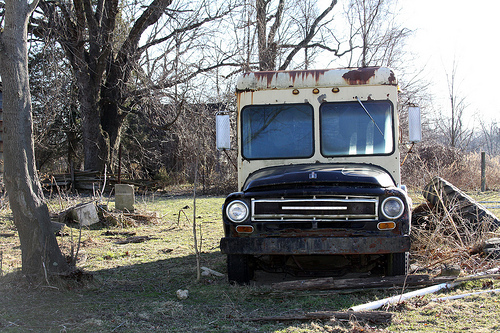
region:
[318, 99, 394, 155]
windshield on right side of truck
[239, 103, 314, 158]
windshield to the left of windshield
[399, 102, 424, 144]
sideview mirror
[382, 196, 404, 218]
headlight is round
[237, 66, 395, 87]
top of truck is rusty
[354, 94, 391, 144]
windshield wiper on windshield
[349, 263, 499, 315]
gray metal pole on ground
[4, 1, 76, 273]
gray tree trunk to the left of truck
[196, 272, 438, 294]
log in front of truck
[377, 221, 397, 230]
small yellow oval light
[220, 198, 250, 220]
headlight on front of truck.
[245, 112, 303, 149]
windshield on front of truck.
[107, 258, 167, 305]
grass on the ground.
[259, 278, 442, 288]
log in front of truck.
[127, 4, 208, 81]
bare tree branches above truck.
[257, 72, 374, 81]
rusted metal on truck.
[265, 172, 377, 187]
black hood of truck.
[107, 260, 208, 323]
truck's shadow on the ground.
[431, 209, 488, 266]
pile of sticks next to truck.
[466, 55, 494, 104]
sunlight in the sky.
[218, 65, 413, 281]
the parked truck is rusty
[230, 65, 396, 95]
the roof of the truck is badly rusted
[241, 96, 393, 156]
windshield wipers are on the truck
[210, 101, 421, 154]
side view mirrors are on the truck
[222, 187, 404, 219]
two headlines on the front the truck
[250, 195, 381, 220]
the grill of the truck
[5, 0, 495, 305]
the trees are bare near the vehicle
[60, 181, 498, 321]
the yard has discarded articles around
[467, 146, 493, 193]
a fence post in the yard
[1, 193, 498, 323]
the grass is green around the truck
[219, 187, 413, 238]
White and yellow truck headlights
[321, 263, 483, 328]
Long white pole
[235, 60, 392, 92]
Rusted top of the truck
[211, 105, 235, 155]
White truck mirror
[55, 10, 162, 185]
Tall dark brown tree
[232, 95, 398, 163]
Two front truck windows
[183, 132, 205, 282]
Tall light brown stick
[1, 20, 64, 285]
Thick light brown tree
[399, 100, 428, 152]
White mirror on side of the truck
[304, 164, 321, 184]
Car brand emblem on the front of the truck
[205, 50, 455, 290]
truck is old and rusted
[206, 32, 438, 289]
truck is old and rusted